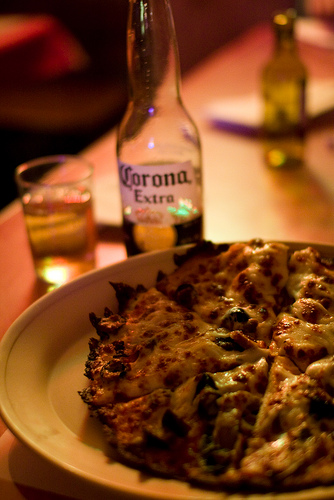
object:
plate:
[0, 240, 333, 499]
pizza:
[77, 241, 333, 490]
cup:
[14, 152, 97, 288]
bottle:
[115, 1, 205, 260]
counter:
[0, 2, 332, 497]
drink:
[21, 187, 94, 287]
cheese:
[95, 247, 333, 480]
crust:
[77, 282, 154, 408]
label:
[117, 159, 197, 224]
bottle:
[259, 9, 308, 172]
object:
[208, 82, 333, 130]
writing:
[117, 164, 191, 203]